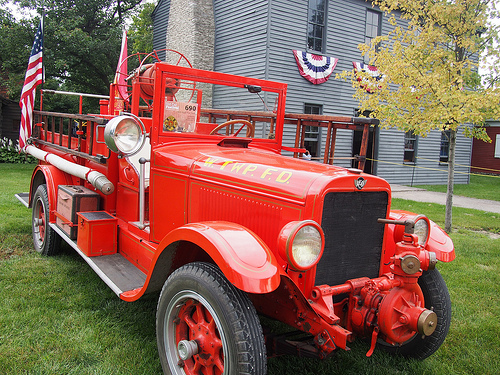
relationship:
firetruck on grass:
[16, 48, 459, 374] [1, 175, 498, 372]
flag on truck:
[18, 18, 45, 154] [12, 48, 459, 373]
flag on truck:
[109, 23, 132, 114] [12, 48, 459, 373]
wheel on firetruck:
[31, 182, 57, 249] [61, 65, 341, 279]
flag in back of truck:
[18, 18, 45, 154] [12, 48, 459, 373]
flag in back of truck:
[108, 30, 129, 115] [12, 48, 459, 373]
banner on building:
[291, 51, 347, 83] [145, 12, 475, 180]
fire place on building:
[150, 0, 212, 132] [151, 0, 484, 189]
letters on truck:
[211, 155, 299, 182] [12, 48, 459, 373]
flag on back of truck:
[108, 30, 129, 115] [12, 48, 459, 373]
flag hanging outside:
[18, 18, 45, 154] [4, 5, 498, 371]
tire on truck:
[371, 262, 452, 360] [12, 48, 459, 373]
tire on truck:
[154, 252, 269, 373] [12, 48, 459, 373]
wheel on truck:
[31, 182, 57, 249] [12, 48, 459, 373]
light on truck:
[385, 209, 434, 259] [12, 48, 459, 373]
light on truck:
[282, 218, 325, 278] [12, 48, 459, 373]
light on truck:
[102, 108, 150, 155] [12, 48, 459, 373]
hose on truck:
[129, 55, 189, 105] [12, 48, 459, 373]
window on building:
[303, 0, 450, 167] [157, 2, 378, 69]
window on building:
[292, 98, 326, 156] [157, 2, 378, 69]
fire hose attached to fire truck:
[17, 139, 116, 195] [23, 58, 449, 373]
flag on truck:
[18, 18, 45, 154] [17, 48, 477, 354]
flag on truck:
[15, 24, 43, 156] [12, 48, 459, 373]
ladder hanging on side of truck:
[22, 101, 114, 166] [24, 46, 405, 338]